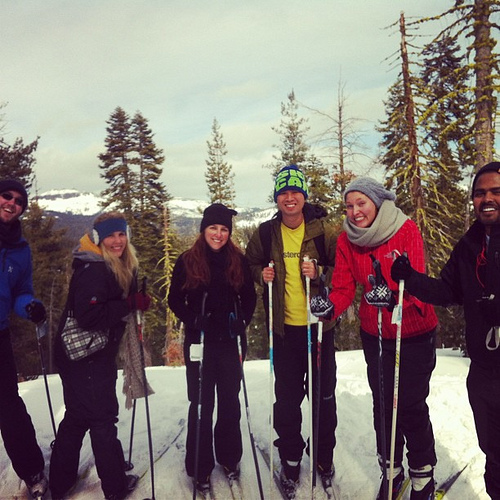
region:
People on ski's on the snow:
[2, 163, 498, 498]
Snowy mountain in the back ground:
[27, 187, 275, 225]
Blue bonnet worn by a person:
[270, 162, 310, 200]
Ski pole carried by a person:
[381, 249, 408, 499]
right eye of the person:
[206, 223, 216, 229]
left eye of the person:
[218, 225, 228, 231]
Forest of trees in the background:
[2, 0, 497, 377]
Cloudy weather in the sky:
[0, 0, 476, 203]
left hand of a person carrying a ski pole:
[259, 260, 278, 282]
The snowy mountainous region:
[0, 349, 498, 499]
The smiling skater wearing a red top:
[316, 175, 445, 497]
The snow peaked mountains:
[26, 188, 403, 232]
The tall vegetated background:
[0, 0, 499, 388]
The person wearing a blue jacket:
[0, 176, 47, 496]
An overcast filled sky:
[0, 0, 499, 210]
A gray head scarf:
[341, 195, 408, 249]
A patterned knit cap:
[272, 163, 309, 198]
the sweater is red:
[332, 237, 440, 328]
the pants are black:
[365, 335, 442, 472]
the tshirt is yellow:
[279, 225, 311, 327]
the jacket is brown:
[246, 223, 286, 333]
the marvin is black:
[201, 199, 233, 232]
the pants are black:
[62, 383, 130, 493]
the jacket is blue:
[1, 238, 36, 326]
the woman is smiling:
[338, 177, 453, 498]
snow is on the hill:
[53, 185, 95, 214]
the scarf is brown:
[128, 321, 148, 396]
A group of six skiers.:
[0, 159, 499, 499]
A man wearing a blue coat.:
[0, 175, 50, 499]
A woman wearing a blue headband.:
[46, 212, 153, 499]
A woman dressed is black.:
[168, 204, 256, 499]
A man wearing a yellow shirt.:
[245, 166, 340, 499]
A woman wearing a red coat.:
[307, 177, 439, 499]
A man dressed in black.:
[390, 159, 499, 499]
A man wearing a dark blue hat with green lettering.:
[242, 167, 338, 499]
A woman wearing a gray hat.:
[308, 177, 440, 499]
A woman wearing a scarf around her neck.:
[307, 177, 439, 499]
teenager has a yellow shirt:
[242, 207, 340, 324]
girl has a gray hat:
[340, 178, 400, 211]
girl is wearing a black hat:
[198, 203, 240, 229]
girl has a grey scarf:
[340, 199, 406, 246]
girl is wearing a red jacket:
[326, 222, 438, 334]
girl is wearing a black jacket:
[54, 256, 138, 380]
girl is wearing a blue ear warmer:
[90, 217, 135, 242]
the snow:
[253, 383, 270, 411]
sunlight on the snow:
[441, 413, 466, 445]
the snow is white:
[346, 463, 356, 482]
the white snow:
[339, 460, 369, 487]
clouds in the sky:
[175, 130, 204, 180]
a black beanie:
[203, 200, 230, 220]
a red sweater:
[343, 250, 360, 283]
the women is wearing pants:
[216, 383, 246, 473]